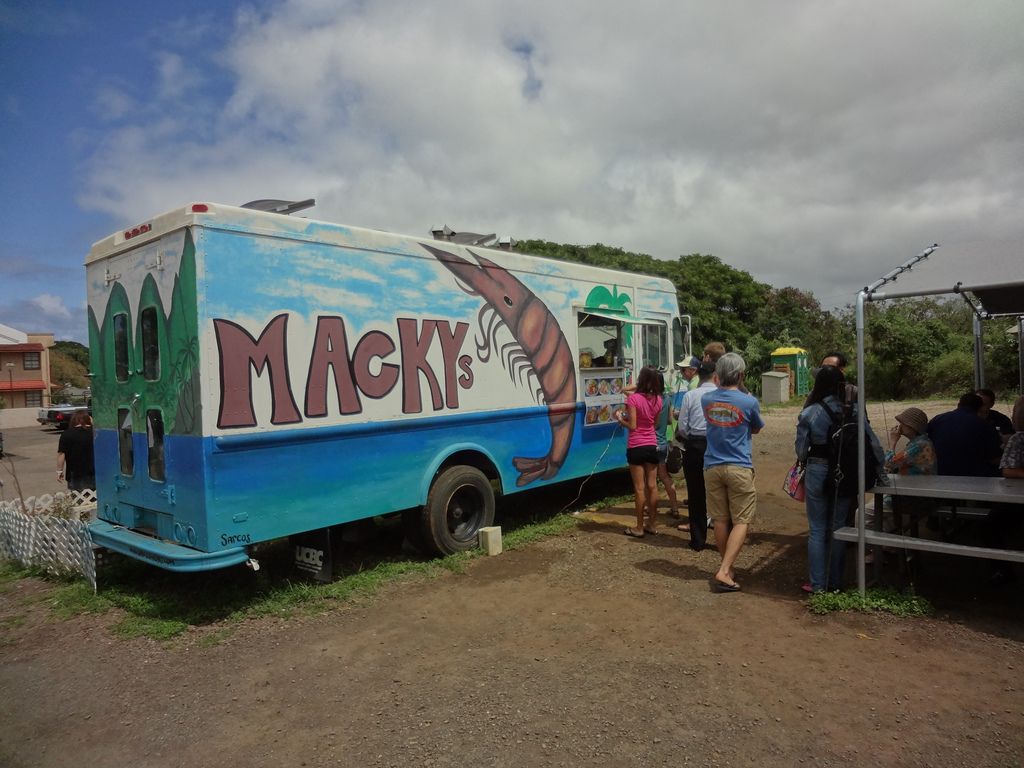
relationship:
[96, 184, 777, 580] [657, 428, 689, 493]
vehicle has front tire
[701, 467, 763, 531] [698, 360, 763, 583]
shorts on man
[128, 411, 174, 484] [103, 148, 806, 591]
window of vehicle